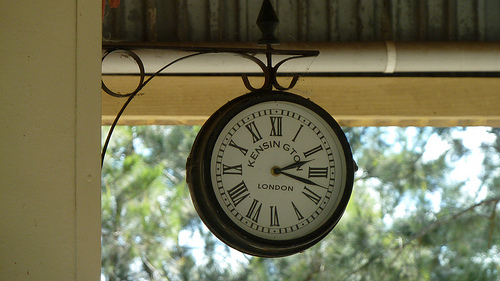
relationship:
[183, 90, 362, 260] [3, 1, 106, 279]
clock hanging by wall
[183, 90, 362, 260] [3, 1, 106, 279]
clock attached to wall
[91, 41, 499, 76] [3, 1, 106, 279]
pipe against wall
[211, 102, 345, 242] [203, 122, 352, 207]
face on clock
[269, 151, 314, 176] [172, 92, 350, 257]
hand on clock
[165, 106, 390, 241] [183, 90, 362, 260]
big hand on clock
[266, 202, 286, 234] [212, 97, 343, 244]
vi on clock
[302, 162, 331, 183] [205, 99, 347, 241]
iii on clock face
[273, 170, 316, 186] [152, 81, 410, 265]
minute hand of clock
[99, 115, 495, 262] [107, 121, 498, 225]
forrest on background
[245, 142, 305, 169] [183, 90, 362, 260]
kensington on clock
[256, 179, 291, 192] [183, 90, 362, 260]
london on clock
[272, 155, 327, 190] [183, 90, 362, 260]
hands on clock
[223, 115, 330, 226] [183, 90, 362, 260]
roman numerals on clock